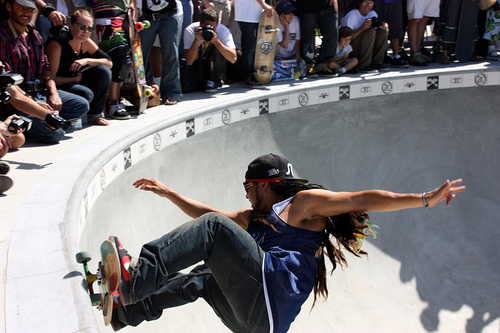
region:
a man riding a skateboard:
[65, 122, 440, 332]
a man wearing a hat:
[206, 136, 346, 241]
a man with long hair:
[241, 127, 369, 273]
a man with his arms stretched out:
[121, 165, 478, 248]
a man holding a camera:
[187, 10, 224, 49]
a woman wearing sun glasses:
[63, 7, 100, 46]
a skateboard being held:
[244, 7, 290, 82]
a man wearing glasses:
[218, 147, 290, 213]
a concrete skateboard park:
[113, 74, 463, 292]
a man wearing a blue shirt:
[173, 138, 376, 331]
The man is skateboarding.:
[111, 118, 363, 331]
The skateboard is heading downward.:
[71, 241, 138, 313]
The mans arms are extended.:
[120, 147, 469, 232]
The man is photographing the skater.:
[192, 12, 227, 52]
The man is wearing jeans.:
[138, 226, 287, 313]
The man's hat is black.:
[248, 145, 323, 189]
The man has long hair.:
[270, 165, 377, 303]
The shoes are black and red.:
[104, 227, 144, 331]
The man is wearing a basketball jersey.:
[236, 204, 330, 326]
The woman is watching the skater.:
[55, 3, 122, 130]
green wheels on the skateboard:
[63, 243, 111, 321]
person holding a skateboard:
[249, 10, 285, 104]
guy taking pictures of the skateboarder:
[190, 7, 240, 57]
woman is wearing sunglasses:
[57, 13, 95, 51]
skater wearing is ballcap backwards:
[229, 143, 305, 188]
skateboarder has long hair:
[270, 173, 423, 306]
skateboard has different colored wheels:
[131, 17, 184, 134]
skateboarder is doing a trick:
[52, 161, 332, 329]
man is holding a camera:
[358, 17, 399, 32]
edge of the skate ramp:
[191, 73, 473, 144]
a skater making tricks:
[66, 126, 473, 331]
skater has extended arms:
[66, 125, 463, 330]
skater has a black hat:
[205, 135, 335, 235]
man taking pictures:
[170, 0, 240, 90]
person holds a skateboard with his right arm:
[235, 0, 285, 82]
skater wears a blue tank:
[72, 120, 473, 325]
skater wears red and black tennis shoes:
[95, 215, 140, 326]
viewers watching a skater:
[1, 0, 488, 120]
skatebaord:
[118, 3, 164, 115]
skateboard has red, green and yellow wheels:
[121, 0, 163, 117]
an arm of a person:
[328, 185, 428, 217]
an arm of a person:
[166, 185, 203, 218]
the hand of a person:
[426, 168, 471, 204]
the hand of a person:
[128, 174, 168, 199]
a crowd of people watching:
[0, 0, 117, 120]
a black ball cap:
[235, 151, 312, 181]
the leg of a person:
[149, 206, 260, 286]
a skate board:
[71, 237, 129, 317]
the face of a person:
[241, 176, 259, 211]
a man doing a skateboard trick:
[79, 140, 402, 325]